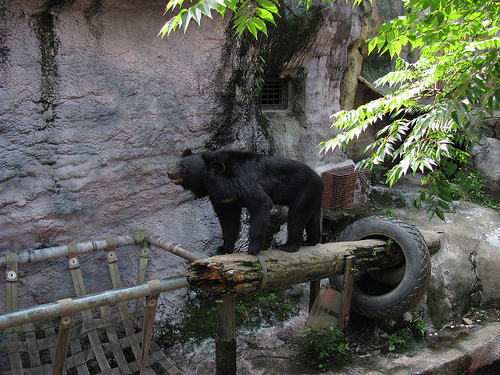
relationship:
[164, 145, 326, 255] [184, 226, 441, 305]
bear standing on top of log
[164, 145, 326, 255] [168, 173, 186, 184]
bear opening mouth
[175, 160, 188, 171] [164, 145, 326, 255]
eye belonging to bear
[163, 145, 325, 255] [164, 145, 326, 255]
bear covering bear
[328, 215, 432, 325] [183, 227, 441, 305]
tire hanging from tree trunk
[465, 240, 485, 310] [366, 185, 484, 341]
crack formed in rock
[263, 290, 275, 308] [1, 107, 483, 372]
plant growing in ground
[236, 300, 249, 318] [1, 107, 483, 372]
plant growing in ground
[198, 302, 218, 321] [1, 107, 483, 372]
plant growing in ground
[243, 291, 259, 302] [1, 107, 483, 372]
plant growing in ground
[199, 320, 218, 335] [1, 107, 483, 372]
plant growing in ground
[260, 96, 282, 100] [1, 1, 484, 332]
bar mounted in wall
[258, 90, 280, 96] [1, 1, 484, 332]
bar mounted in wall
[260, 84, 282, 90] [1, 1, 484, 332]
bar mounted in wall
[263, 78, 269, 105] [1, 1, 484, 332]
bar mounted in wall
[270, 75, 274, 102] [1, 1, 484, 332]
bar mounted in wall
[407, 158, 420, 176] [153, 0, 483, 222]
leaf growing on tree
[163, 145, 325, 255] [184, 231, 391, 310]
bear on log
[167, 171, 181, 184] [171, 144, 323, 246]
tongue of bear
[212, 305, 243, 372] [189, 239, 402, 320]
post holding log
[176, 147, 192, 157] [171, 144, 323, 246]
left ear of bear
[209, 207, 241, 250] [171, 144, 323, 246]
left leg of bear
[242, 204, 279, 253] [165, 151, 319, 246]
right leg of bear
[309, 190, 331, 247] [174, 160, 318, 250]
left leg of bear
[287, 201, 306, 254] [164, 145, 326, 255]
right leg of bear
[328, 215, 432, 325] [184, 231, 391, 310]
tire around log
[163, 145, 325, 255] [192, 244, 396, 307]
bear standing on a log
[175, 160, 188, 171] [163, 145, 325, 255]
eye of bear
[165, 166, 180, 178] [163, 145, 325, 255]
nose of bear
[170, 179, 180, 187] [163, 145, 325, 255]
mouth of bear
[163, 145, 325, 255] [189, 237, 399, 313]
bear standing on a log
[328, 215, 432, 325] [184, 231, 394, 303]
tire around a log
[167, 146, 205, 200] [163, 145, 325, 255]
head of a bear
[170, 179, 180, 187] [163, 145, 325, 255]
mouth of a bear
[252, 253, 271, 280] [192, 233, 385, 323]
leaves on log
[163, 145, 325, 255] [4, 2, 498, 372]
bear in enclosure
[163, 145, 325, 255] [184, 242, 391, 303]
bear standing on elevated log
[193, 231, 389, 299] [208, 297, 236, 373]
log elevated on post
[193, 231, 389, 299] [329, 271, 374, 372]
log elevated on post